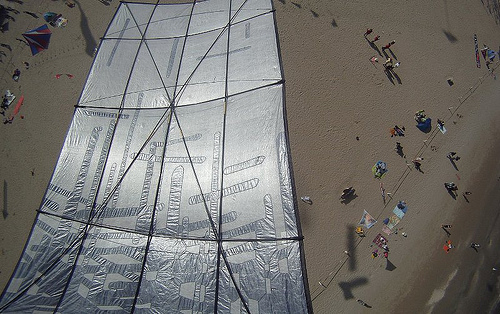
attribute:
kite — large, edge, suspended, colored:
[81, 1, 254, 204]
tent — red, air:
[22, 23, 51, 48]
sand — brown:
[384, 5, 426, 17]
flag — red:
[12, 93, 33, 133]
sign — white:
[382, 206, 426, 233]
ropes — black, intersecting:
[202, 14, 246, 29]